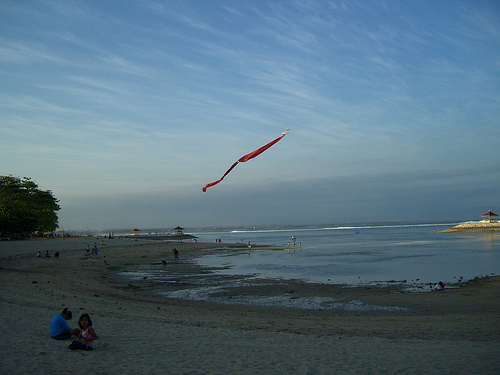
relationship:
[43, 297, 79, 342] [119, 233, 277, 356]
person on beach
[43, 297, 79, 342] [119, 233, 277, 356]
person in beach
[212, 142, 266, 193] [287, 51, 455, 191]
kite in sky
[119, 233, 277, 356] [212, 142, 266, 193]
beach has kite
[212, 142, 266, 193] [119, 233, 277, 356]
kite on beach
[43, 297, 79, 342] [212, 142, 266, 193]
person near kite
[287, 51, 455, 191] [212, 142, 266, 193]
sky near kite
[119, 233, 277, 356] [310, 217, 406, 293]
beach has water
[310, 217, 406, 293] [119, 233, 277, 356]
water on beach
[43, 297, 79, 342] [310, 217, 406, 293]
person near water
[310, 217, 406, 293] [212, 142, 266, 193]
water below kite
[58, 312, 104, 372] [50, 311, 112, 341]
person wearing shirt